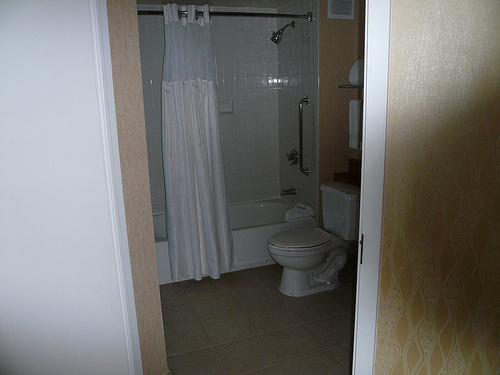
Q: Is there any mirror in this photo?
A: No, there are no mirrors.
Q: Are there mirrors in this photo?
A: No, there are no mirrors.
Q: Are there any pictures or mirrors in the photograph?
A: No, there are no mirrors or pictures.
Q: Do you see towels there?
A: Yes, there is a towel.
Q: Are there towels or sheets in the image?
A: Yes, there is a towel.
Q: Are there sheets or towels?
A: Yes, there is a towel.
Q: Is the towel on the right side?
A: Yes, the towel is on the right of the image.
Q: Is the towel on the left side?
A: No, the towel is on the right of the image.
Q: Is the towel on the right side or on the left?
A: The towel is on the right of the image.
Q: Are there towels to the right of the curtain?
A: Yes, there is a towel to the right of the curtain.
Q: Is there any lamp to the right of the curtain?
A: No, there is a towel to the right of the curtain.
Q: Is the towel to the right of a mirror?
A: No, the towel is to the right of the curtain.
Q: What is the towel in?
A: The towel is in the shower.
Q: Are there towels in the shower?
A: Yes, there is a towel in the shower.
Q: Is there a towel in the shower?
A: Yes, there is a towel in the shower.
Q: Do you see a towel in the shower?
A: Yes, there is a towel in the shower.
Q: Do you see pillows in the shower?
A: No, there is a towel in the shower.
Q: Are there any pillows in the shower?
A: No, there is a towel in the shower.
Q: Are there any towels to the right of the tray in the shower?
A: Yes, there is a towel to the right of the tray.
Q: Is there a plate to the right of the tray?
A: No, there is a towel to the right of the tray.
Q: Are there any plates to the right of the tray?
A: No, there is a towel to the right of the tray.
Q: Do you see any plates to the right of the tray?
A: No, there is a towel to the right of the tray.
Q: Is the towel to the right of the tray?
A: Yes, the towel is to the right of the tray.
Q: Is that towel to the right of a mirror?
A: No, the towel is to the right of the tray.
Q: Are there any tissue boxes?
A: No, there are no tissue boxes.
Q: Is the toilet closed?
A: Yes, the toilet is closed.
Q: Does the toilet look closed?
A: Yes, the toilet is closed.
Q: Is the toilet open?
A: No, the toilet is closed.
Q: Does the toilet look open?
A: No, the toilet is closed.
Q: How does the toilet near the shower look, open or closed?
A: The toilet is closed.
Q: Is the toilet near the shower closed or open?
A: The toilet is closed.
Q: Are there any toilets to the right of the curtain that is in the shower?
A: Yes, there is a toilet to the right of the curtain.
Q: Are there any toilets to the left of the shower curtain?
A: No, the toilet is to the right of the curtain.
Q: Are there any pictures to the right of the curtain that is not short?
A: No, there is a toilet to the right of the curtain.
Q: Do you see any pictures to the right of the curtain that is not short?
A: No, there is a toilet to the right of the curtain.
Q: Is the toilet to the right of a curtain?
A: Yes, the toilet is to the right of a curtain.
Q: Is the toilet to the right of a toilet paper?
A: No, the toilet is to the right of a curtain.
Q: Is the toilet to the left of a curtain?
A: No, the toilet is to the right of a curtain.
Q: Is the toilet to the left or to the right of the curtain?
A: The toilet is to the right of the curtain.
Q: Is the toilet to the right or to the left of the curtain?
A: The toilet is to the right of the curtain.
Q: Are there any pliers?
A: No, there are no pliers.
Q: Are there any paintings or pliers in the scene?
A: No, there are no pliers or paintings.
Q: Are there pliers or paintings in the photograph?
A: No, there are no pliers or paintings.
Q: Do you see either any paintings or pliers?
A: No, there are no pliers or paintings.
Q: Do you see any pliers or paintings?
A: No, there are no pliers or paintings.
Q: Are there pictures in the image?
A: No, there are no pictures.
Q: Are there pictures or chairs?
A: No, there are no pictures or chairs.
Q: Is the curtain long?
A: Yes, the curtain is long.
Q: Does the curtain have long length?
A: Yes, the curtain is long.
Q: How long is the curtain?
A: The curtain is long.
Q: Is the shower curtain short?
A: No, the curtain is long.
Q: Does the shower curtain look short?
A: No, the curtain is long.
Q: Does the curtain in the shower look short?
A: No, the curtain is long.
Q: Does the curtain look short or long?
A: The curtain is long.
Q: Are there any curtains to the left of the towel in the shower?
A: Yes, there is a curtain to the left of the towel.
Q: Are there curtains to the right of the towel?
A: No, the curtain is to the left of the towel.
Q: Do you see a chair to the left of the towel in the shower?
A: No, there is a curtain to the left of the towel.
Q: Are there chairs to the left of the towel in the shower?
A: No, there is a curtain to the left of the towel.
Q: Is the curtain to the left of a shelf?
A: No, the curtain is to the left of the towel.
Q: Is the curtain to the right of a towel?
A: No, the curtain is to the left of a towel.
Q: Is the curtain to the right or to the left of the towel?
A: The curtain is to the left of the towel.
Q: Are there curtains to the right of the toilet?
A: No, the curtain is to the left of the toilet.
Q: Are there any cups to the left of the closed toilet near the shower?
A: No, there is a curtain to the left of the toilet.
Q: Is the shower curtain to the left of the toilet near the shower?
A: Yes, the curtain is to the left of the toilet.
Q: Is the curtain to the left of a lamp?
A: No, the curtain is to the left of the toilet.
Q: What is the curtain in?
A: The curtain is in the shower.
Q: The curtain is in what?
A: The curtain is in the shower.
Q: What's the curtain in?
A: The curtain is in the shower.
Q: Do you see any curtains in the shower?
A: Yes, there is a curtain in the shower.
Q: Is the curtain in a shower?
A: Yes, the curtain is in a shower.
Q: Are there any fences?
A: No, there are no fences.